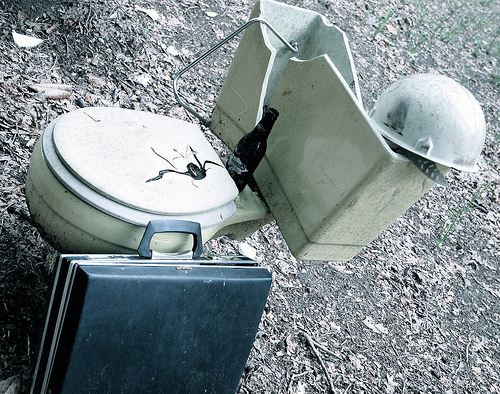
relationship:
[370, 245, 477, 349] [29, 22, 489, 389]
leaves on ground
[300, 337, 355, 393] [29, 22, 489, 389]
twig on ground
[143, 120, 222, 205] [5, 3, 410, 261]
stain on toilet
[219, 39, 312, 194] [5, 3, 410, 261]
crack in toilet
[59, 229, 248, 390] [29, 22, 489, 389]
briefcase on ground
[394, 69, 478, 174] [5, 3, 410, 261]
helmet on toilet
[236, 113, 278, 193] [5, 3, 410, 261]
bottle on toilet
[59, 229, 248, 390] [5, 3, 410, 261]
briefcase on toilet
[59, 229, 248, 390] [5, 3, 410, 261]
briefcase against toilet